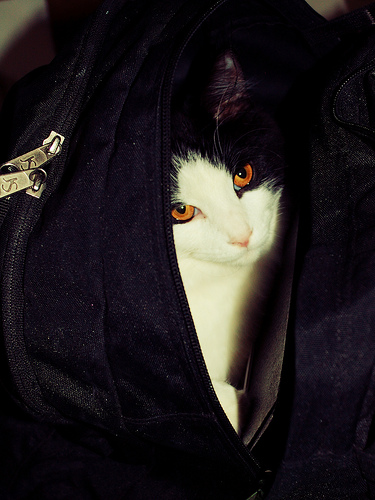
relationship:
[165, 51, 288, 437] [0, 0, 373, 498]
cat in bag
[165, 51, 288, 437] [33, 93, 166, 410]
cat in bag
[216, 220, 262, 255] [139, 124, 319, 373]
nose of a cat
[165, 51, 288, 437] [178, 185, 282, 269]
cat has whiskers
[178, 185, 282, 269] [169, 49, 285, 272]
whiskers on head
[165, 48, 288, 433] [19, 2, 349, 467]
cat in bag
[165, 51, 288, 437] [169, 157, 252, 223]
cat has cat's eyes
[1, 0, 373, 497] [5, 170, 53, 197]
luggage has zipper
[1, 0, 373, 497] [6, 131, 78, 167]
luggage has zipper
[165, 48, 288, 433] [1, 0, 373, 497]
cat inside luggage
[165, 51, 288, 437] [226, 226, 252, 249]
cat has nose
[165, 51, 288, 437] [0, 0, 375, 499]
cat inside bag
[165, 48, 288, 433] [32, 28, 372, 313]
cat inside bag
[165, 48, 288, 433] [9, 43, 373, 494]
cat in bag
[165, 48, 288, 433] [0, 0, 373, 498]
cat in bag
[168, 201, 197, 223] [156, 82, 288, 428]
eye on cat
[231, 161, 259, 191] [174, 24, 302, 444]
eye on cat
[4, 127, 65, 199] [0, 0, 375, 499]
zipper on bag